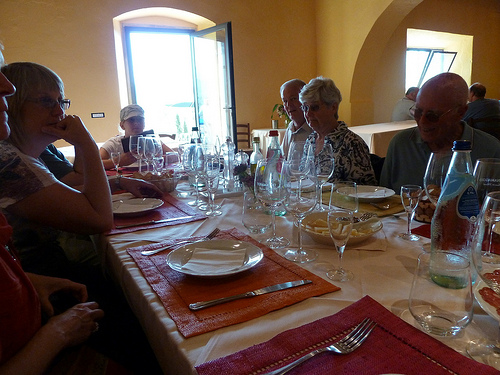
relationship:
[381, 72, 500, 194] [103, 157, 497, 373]
man sitting on table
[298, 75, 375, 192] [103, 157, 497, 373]
lady sitting on table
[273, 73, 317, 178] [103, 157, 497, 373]
person sitting on table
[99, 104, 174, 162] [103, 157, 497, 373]
boy sitting on table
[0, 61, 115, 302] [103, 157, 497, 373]
lady sitting on table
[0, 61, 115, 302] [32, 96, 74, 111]
lady wearing glasses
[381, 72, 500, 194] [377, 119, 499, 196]
man wearing blue shirt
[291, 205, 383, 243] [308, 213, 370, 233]
bowl with pasta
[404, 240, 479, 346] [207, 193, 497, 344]
glass on table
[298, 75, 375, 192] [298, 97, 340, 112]
lady wears glasses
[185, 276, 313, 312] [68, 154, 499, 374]
utensil on table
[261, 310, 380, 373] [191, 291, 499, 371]
fork on cloth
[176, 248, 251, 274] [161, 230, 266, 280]
napkin on plate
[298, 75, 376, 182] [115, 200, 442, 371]
lady at table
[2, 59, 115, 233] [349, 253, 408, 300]
lady at table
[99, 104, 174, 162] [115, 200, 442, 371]
boy at table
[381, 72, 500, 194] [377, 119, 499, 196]
man has blue shirt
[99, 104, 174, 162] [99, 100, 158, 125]
boy has hat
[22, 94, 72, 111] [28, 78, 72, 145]
glasses on face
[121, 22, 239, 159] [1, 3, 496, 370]
door on room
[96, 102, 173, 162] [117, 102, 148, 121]
boy has hat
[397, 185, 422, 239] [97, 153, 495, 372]
glass on tablecloth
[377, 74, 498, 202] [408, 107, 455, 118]
man has glasses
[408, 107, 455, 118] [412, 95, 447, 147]
glasses on face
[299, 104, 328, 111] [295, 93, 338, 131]
glasses on face